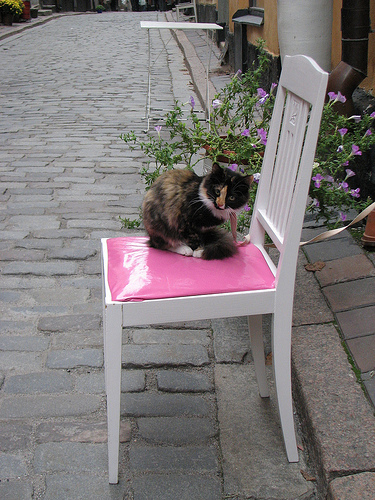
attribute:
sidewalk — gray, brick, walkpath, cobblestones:
[0, 10, 322, 498]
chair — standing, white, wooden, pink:
[100, 53, 330, 485]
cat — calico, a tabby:
[139, 161, 254, 256]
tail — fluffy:
[204, 227, 238, 260]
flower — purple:
[328, 91, 346, 109]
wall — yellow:
[195, 0, 374, 138]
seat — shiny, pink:
[106, 235, 274, 303]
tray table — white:
[140, 16, 221, 132]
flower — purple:
[338, 127, 349, 139]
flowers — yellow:
[2, 0, 30, 18]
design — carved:
[285, 95, 303, 136]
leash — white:
[230, 200, 374, 252]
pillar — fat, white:
[276, 1, 333, 71]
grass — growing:
[332, 319, 374, 404]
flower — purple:
[312, 173, 325, 189]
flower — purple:
[256, 127, 268, 144]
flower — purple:
[349, 187, 360, 202]